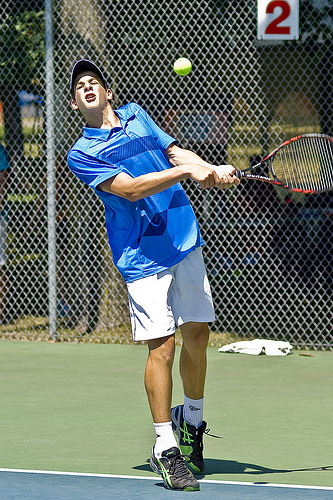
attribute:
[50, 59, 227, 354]
man — playing, looking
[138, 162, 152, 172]
shirt — polo, blue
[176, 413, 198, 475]
shoes — tennis, green, black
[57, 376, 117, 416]
tennis court — green, blue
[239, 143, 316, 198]
tennis racket — black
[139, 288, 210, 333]
shorts — white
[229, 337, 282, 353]
cloth — white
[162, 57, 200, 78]
tennis ball — air, yellow, green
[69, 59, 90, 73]
cap — baseball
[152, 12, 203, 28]
fence — tall, metal, chain, chain link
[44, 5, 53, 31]
post — metal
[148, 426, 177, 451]
sock — white, crew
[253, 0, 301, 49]
sign — white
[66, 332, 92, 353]
turf — green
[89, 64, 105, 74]
visor — black